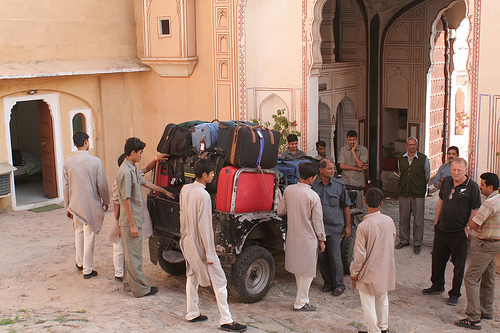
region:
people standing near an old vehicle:
[70, 106, 497, 329]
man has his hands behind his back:
[394, 138, 429, 253]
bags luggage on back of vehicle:
[219, 116, 280, 217]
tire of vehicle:
[232, 240, 272, 303]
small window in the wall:
[156, 17, 173, 37]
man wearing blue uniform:
[319, 154, 348, 299]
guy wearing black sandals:
[452, 316, 478, 327]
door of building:
[6, 98, 61, 210]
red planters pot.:
[379, 145, 399, 172]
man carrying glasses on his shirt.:
[446, 188, 456, 200]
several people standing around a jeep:
[13, 78, 471, 310]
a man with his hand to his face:
[341, 120, 371, 171]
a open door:
[25, 88, 56, 222]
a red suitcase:
[218, 168, 274, 210]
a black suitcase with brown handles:
[225, 121, 288, 166]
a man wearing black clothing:
[426, 155, 476, 282]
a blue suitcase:
[185, 115, 222, 153]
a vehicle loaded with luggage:
[135, 109, 298, 230]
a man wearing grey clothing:
[325, 158, 343, 252]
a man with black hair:
[185, 154, 216, 188]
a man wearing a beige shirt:
[64, 132, 110, 279]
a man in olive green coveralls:
[114, 135, 174, 297]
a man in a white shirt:
[176, 159, 246, 331]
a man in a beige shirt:
[277, 163, 327, 314]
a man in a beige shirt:
[350, 187, 397, 331]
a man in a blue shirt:
[311, 158, 353, 295]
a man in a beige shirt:
[455, 171, 499, 328]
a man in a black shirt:
[421, 158, 481, 305]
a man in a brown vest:
[395, 138, 431, 253]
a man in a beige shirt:
[339, 128, 369, 214]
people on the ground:
[61, 92, 353, 312]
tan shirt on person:
[351, 215, 386, 278]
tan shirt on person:
[260, 199, 327, 243]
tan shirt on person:
[171, 182, 205, 254]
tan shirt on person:
[57, 162, 92, 196]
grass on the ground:
[32, 313, 72, 328]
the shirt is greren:
[390, 169, 421, 191]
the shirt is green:
[112, 172, 142, 184]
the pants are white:
[213, 300, 231, 308]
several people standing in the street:
[37, 85, 499, 320]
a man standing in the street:
[54, 125, 114, 291]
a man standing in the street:
[113, 133, 160, 301]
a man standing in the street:
[175, 156, 250, 330]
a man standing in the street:
[276, 159, 330, 317]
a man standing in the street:
[347, 186, 399, 330]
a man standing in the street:
[463, 170, 498, 330]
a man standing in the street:
[418, 156, 477, 310]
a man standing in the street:
[392, 130, 433, 255]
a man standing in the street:
[335, 125, 370, 194]